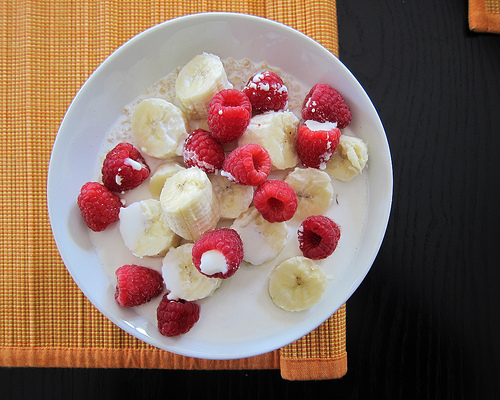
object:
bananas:
[159, 167, 221, 240]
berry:
[222, 143, 269, 186]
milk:
[96, 75, 332, 267]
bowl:
[47, 11, 393, 360]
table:
[0, 0, 348, 381]